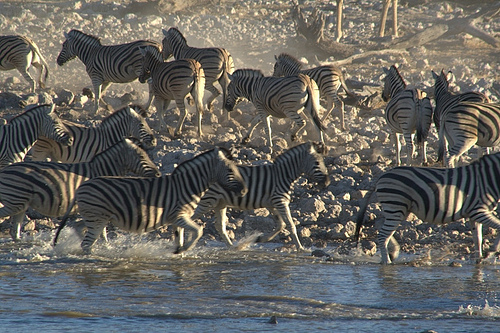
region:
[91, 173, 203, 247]
this is a zebra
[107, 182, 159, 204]
the zebra has black and white strips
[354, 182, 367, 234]
this is the tail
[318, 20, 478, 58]
this is a wood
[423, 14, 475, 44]
the wood is dry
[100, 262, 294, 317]
this is a river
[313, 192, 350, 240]
these are the rocks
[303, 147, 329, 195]
this is the head of the zebra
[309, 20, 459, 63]
the wood is lying on the ground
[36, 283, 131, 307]
the water is calm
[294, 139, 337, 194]
the head of a zebra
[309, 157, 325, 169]
the eye of a zebra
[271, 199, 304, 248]
the leg of a zebra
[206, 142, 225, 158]
the ear of a zebra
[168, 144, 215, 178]
the mane of a zebra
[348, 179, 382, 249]
the tail of a zebra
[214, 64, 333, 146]
a black and white zebra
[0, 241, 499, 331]
a small body of water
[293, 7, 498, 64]
a large brown log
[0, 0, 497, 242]
a rocky shore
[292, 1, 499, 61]
giant piece of drift wood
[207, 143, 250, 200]
zebra's head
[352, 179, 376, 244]
zebra's wet tail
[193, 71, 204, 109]
zebra with an all white tail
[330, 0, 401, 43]
three small tree trunks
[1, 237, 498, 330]
river with zebras running through it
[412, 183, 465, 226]
fat zebra belly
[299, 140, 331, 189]
zebra's head facing right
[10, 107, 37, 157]
thick zebra neck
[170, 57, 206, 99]
zebra's large rear end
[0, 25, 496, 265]
herd of zebras in the wild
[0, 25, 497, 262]
wild herd of zebras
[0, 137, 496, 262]
four zebras running in the water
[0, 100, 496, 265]
six zebras running and walking east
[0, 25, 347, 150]
six zebras walking west on rocks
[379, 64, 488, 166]
two zebras standing on rocks facing north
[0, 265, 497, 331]
water behind the field of rocks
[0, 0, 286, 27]
grey rocks on the ground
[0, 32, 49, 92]
the back end of a zebra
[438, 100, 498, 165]
back end of zebra heading east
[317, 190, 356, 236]
part of a ground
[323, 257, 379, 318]
part of a water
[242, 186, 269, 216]
part of a stomach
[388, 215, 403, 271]
part of a thigh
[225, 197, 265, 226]
edge of a stomach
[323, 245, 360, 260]
edge of a shore